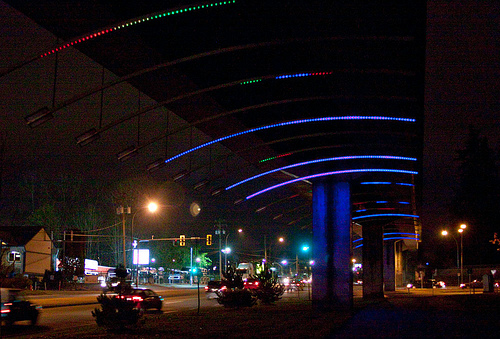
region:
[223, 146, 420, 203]
a couple of neon lights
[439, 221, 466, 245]
street lights on a pole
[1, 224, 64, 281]
a building in a yard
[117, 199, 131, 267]
a electric pole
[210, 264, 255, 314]
a tree along the road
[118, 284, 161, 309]
a car on a street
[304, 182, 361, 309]
a concert post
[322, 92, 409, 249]
a group of neon lights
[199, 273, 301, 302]
cars going down a street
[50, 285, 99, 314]
barrier between a street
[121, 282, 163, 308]
a moving car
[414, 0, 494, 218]
a black night sky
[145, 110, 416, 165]
blue arched decorative lighting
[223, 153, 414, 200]
blue arched decorative lighting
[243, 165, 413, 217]
blue and purple decorative lighting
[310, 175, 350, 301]
a concrete support pillar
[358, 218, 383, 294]
a concrete support pillar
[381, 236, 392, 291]
a concrete support pillar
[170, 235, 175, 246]
an electric traffic signal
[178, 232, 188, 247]
an electric traffic signal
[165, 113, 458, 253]
blue strips of light in the sky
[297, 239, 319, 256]
green traffic light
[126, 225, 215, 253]
a traffic signal arm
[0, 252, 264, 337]
cars driving down the road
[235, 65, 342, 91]
multicolored strip of light in the sky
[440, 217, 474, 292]
light post in the sky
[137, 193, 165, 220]
a yellow light shining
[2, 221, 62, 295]
a small house on the side of the road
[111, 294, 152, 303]
red tail lights on a car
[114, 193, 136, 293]
telephone pole on the side of the road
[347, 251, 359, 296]
edge of a building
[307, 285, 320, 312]
part of a path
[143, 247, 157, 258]
part of a light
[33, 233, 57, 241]
part of a house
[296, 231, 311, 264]
part of a light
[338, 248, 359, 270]
part of a pillar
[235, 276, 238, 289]
part of a bush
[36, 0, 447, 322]
a colorfully lit archway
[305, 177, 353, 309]
two posts with blue light on them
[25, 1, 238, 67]
a row of green, yellow and red neon lights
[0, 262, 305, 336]
six cars driving down a street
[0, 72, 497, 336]
cars approaching a stoplight at night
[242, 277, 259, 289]
the tail lights of a car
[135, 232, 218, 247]
two traffic lights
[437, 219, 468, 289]
three street lights close together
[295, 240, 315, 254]
a green stop light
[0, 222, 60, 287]
a white building with a black roof